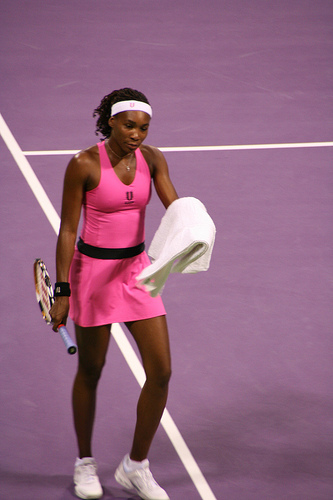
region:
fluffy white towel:
[140, 191, 222, 296]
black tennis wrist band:
[49, 280, 76, 299]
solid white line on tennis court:
[163, 430, 221, 492]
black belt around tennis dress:
[81, 237, 162, 264]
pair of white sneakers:
[61, 450, 181, 495]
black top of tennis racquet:
[61, 340, 94, 359]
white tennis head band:
[111, 86, 164, 123]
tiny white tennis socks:
[123, 448, 152, 472]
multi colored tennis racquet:
[27, 257, 83, 359]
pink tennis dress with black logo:
[66, 131, 195, 365]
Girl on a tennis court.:
[32, 84, 202, 498]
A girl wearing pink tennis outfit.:
[67, 144, 164, 327]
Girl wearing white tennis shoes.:
[69, 454, 173, 499]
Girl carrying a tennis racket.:
[20, 255, 78, 356]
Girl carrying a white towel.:
[136, 193, 224, 296]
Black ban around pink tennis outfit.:
[75, 231, 156, 259]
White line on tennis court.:
[166, 434, 226, 499]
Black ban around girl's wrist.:
[52, 279, 73, 301]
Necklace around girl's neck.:
[107, 143, 141, 175]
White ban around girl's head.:
[107, 98, 154, 121]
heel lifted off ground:
[101, 458, 186, 492]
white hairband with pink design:
[90, 97, 162, 114]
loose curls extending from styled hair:
[82, 84, 111, 150]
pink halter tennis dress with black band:
[62, 135, 183, 348]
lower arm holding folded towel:
[108, 196, 237, 298]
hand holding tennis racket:
[16, 253, 81, 361]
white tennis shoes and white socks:
[64, 449, 169, 496]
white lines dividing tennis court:
[2, 137, 250, 403]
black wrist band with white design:
[48, 268, 66, 301]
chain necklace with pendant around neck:
[91, 137, 147, 182]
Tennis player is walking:
[32, 85, 215, 498]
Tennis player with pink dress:
[30, 88, 215, 498]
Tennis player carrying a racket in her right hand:
[24, 83, 229, 498]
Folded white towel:
[140, 199, 220, 296]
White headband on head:
[109, 99, 155, 117]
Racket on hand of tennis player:
[28, 254, 81, 353]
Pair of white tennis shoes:
[69, 452, 178, 498]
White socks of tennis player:
[72, 453, 151, 468]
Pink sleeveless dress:
[70, 137, 167, 327]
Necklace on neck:
[103, 140, 140, 170]